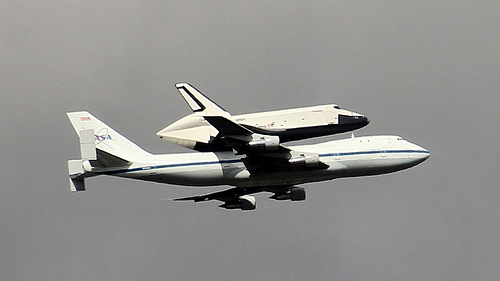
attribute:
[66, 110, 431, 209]
plane — white, large, windowless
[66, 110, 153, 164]
tail — tall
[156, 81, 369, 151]
space shuttle — white, black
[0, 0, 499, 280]
sky — grey, gray, hazy